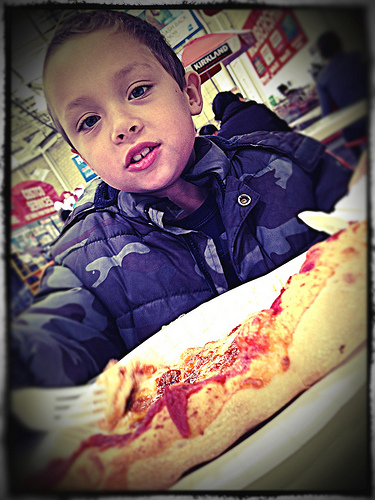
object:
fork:
[10, 376, 109, 436]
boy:
[10, 12, 369, 414]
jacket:
[0, 134, 365, 427]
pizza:
[22, 219, 374, 489]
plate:
[30, 218, 367, 490]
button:
[234, 192, 253, 208]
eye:
[126, 84, 158, 104]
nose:
[108, 105, 142, 149]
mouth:
[121, 138, 161, 173]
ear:
[181, 71, 204, 119]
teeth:
[139, 147, 149, 157]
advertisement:
[250, 55, 265, 77]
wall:
[160, 12, 372, 101]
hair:
[35, 12, 188, 150]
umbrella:
[179, 29, 236, 73]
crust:
[296, 293, 355, 350]